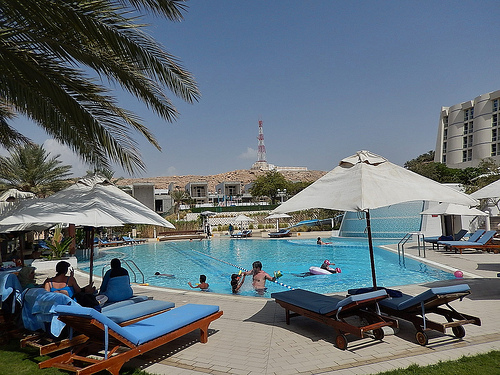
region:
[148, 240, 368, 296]
people playing in a pool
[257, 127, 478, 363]
large canopy umbrella at pool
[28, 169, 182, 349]
sitting in the shade at the pool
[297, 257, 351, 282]
playing in white and purple float toy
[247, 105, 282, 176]
red and white metal pillar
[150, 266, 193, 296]
swimming under the water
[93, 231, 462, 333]
clear water in a blue pool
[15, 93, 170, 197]
leaves of palm trees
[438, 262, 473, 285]
pink beach ball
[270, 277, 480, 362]
lounge chairs with wheels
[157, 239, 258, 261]
this is a swimming pool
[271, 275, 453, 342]
these are beach chairs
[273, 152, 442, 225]
an umbrella is above the beach chairs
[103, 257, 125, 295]
this is a woman sitted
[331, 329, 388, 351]
the beach chair has wheels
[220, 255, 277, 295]
the man and the child are playing in the pool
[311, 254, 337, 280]
the child is on a floater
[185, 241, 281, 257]
the swimming pool is blue in color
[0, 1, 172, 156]
these are palm leaves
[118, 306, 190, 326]
the seats are blue in color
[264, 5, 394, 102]
part of the blue sky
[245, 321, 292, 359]
part of a swimming pool side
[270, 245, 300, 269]
water in a swimming pool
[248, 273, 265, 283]
chest of a man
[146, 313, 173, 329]
part of a blue surface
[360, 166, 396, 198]
part of an umnrella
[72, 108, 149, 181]
some leaves of a palmtree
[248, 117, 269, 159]
part of a network tower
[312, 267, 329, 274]
part of a white floater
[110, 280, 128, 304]
part of a towel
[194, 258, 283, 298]
Three people in a swimming pool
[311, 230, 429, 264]
A person in a swimming pool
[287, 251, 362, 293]
A person in a swimming pool with a floatation device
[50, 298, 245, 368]
A pool lounge chair with a blue cushion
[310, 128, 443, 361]
A white pool umbrella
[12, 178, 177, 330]
Two people sitting in the shade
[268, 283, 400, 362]
A pool chair with wheels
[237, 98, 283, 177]
A red and white tower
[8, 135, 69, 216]
A palm tree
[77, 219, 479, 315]
A swimming pool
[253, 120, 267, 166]
A red and white cell phone tower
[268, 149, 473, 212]
A canvas beach umbrella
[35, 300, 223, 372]
A blue and brown lounge chair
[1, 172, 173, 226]
A white canvas beach umbrella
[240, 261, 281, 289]
A boy playing in the pool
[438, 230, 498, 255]
Two blue and brown lounge chairs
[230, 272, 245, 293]
A child playing in the pool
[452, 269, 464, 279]
A purple plastic ball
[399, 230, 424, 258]
Swimming pool railings